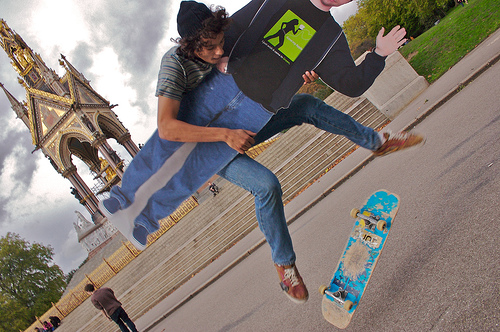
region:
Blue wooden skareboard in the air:
[274, 226, 440, 327]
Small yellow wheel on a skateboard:
[342, 200, 364, 230]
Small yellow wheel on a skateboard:
[373, 211, 390, 232]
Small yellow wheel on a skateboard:
[339, 296, 365, 318]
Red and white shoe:
[358, 118, 442, 161]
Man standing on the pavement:
[72, 276, 160, 330]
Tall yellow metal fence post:
[28, 311, 53, 331]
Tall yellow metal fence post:
[86, 266, 110, 290]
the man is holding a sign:
[107, 27, 482, 259]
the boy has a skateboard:
[309, 198, 473, 321]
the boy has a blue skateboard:
[300, 222, 400, 317]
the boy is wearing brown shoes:
[239, 248, 406, 318]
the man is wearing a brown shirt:
[70, 285, 288, 313]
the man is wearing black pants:
[101, 308, 136, 329]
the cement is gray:
[175, 299, 232, 328]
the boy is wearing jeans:
[237, 173, 385, 316]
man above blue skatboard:
[67, 0, 465, 321]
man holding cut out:
[76, 7, 443, 252]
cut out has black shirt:
[230, 3, 402, 113]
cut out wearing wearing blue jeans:
[89, 70, 282, 250]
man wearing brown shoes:
[217, 112, 446, 309]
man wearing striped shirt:
[136, 37, 240, 121]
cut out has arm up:
[332, 9, 429, 109]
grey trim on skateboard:
[313, 173, 442, 328]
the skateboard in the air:
[285, 183, 437, 330]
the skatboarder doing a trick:
[150, 0, 431, 287]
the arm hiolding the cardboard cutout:
[142, 57, 255, 164]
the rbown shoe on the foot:
[372, 124, 427, 166]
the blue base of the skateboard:
[328, 181, 398, 308]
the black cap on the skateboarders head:
[170, 0, 213, 40]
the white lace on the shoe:
[281, 263, 301, 291]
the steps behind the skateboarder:
[168, 202, 252, 282]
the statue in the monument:
[77, 154, 124, 183]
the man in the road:
[79, 277, 140, 331]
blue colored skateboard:
[305, 184, 406, 330]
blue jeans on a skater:
[196, 100, 387, 269]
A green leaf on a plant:
[12, 249, 16, 252]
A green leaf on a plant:
[9, 264, 13, 267]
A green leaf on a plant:
[35, 299, 37, 300]